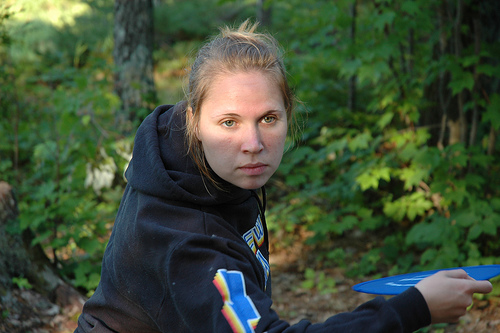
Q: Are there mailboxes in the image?
A: No, there are no mailboxes.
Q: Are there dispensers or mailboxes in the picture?
A: No, there are no mailboxes or dispensers.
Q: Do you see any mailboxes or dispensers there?
A: No, there are no mailboxes or dispensers.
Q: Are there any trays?
A: No, there are no trays.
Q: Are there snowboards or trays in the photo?
A: No, there are no trays or snowboards.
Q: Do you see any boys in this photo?
A: No, there are no boys.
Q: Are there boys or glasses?
A: No, there are no boys or glasses.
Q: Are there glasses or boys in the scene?
A: No, there are no boys or glasses.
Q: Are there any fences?
A: No, there are no fences.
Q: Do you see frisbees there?
A: Yes, there is a frisbee.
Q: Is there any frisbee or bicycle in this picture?
A: Yes, there is a frisbee.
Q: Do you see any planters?
A: No, there are no planters.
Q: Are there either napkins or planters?
A: No, there are no planters or napkins.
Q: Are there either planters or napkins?
A: No, there are no planters or napkins.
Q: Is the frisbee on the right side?
A: Yes, the frisbee is on the right of the image.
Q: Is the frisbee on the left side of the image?
A: No, the frisbee is on the right of the image.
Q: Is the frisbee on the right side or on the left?
A: The frisbee is on the right of the image.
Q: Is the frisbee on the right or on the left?
A: The frisbee is on the right of the image.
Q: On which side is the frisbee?
A: The frisbee is on the right of the image.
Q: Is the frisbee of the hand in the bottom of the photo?
A: Yes, the frisbee is in the bottom of the image.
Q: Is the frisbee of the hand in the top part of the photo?
A: No, the frisbee is in the bottom of the image.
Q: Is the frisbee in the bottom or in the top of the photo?
A: The frisbee is in the bottom of the image.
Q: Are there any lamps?
A: No, there are no lamps.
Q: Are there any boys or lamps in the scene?
A: No, there are no lamps or boys.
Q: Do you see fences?
A: No, there are no fences.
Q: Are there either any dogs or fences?
A: No, there are no fences or dogs.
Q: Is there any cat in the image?
A: No, there are no cats.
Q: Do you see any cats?
A: No, there are no cats.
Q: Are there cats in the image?
A: No, there are no cats.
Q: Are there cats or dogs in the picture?
A: No, there are no cats or dogs.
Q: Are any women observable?
A: Yes, there is a woman.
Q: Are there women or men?
A: Yes, there is a woman.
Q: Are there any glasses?
A: No, there are no glasses.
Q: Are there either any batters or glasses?
A: No, there are no glasses or batters.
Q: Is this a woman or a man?
A: This is a woman.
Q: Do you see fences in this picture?
A: No, there are no fences.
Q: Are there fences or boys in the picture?
A: No, there are no fences or boys.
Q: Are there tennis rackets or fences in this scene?
A: No, there are no fences or tennis rackets.